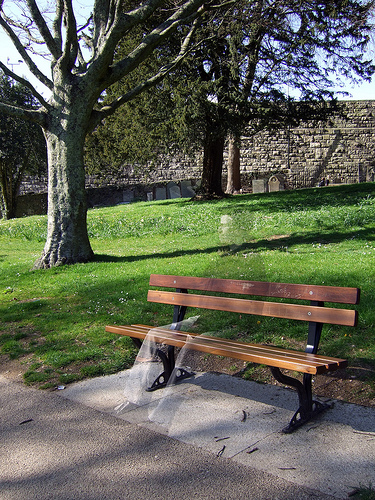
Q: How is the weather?
A: Sunny.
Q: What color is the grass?
A: Green.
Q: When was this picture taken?
A: Daytime.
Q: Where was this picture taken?
A: A park.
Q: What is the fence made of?
A: Stone.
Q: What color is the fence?
A: Grey.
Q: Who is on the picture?
A: A ghost.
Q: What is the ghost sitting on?
A: A bench.